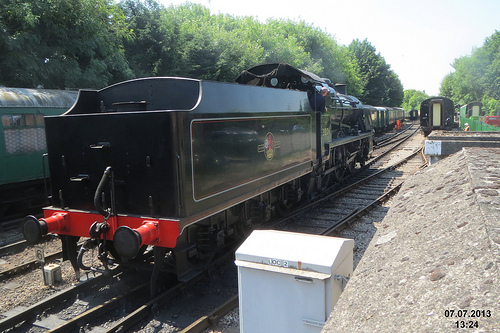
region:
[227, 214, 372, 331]
white box with tiny black letters near the top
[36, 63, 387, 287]
train engine on railroad tracks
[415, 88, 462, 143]
back of train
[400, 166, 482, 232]
cement embankment dotted with round stones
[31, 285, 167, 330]
rusted railroad tracks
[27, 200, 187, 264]
red bar back of train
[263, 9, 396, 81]
tree line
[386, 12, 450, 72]
slightly overcast sky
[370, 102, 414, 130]
long train fading into the distance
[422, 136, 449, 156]
white box on side of wall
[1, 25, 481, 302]
the train cars are black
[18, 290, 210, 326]
the train track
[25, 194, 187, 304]
the back of the train car is red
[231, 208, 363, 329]
an electrical box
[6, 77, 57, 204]
an old train car is green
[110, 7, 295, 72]
lots of trees line the track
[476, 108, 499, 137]
a red truck is parked to the side of the track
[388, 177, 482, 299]
the side of the track is lined in concrete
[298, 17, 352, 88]
there is smoke coming out of the locomotive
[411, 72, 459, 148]
the back door of the train is white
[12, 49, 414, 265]
train is black with red bumber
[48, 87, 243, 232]
train is black with red bumber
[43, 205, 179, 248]
Back red part of a train.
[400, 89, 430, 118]
Group of light colored trees in the distance.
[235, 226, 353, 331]
White electrical box by the train tracks.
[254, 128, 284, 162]
Circle logo on the side of the black train.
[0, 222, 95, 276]
Small part of train track.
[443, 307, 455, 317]
Black numbers that say 07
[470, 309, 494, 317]
The date 2013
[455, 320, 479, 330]
13:24 in black writing.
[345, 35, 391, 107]
Large dark green pine tree.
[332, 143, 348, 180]
Large black wheel on side of black train.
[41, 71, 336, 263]
black and red train car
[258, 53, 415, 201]
a black train engine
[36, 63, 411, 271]
train on train tracks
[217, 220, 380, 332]
control box for train tracks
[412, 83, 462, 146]
back of a train car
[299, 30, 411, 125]
trees on the side of train tracks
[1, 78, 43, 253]
a tank train car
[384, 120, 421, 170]
switch over train tracks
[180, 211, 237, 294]
train wheels on a train car